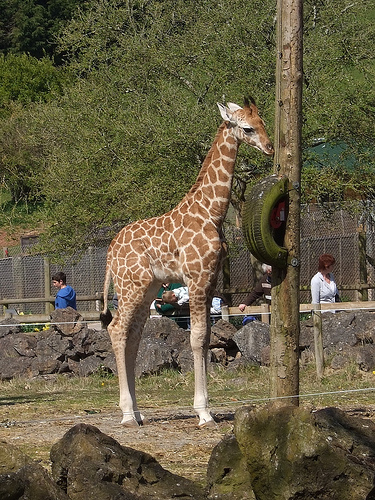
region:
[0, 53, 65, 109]
green leaves on tree top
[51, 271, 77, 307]
boy wearing blue hoodie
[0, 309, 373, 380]
uneven stone wall of enclosure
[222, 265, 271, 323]
man with hand on wood fence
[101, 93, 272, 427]
side view of young standing giraffe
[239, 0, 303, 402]
wood pole with half tire under rope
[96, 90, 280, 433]
young brown and white giraffe standing near wooden pole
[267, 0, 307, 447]
thick brown wooden pole near giraffe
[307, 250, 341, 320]
woman wearing white shirt walking near giraffe enclosure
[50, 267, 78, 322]
person wearing blue coat walking near giraffe enclosure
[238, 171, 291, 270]
green and black half of tire attached to wooden pole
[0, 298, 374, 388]
light brown wooden fence around giraffe enclosure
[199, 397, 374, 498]
large gray black and green stone near giraffe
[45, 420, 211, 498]
large black green and gray rock near giraffe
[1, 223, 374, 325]
tall metal fence near giraffe enclosure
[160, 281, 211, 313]
person wearing white outfit hanging over side of fence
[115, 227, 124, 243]
brown spot on giraffe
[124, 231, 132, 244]
brown spot on giraffe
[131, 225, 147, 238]
brown spot on giraffe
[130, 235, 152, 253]
brown spot on giraffe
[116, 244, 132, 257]
brown spot on giraffe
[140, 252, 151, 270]
brown spot on giraffe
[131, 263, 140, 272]
brown spot on giraffe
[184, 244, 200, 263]
brown spot on giraffe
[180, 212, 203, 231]
brown spot on giraffe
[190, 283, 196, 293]
brown spot on giraffe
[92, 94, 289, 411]
The giraffe is a young one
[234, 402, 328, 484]
The moss is green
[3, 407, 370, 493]
The three rocks in the front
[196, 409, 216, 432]
The front hooves of the giraffe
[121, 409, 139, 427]
The back hooves of the giraffe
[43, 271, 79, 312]
The boy in the blue hoodie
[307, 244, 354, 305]
The woman in the white shirt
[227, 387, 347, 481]
The rock has moss on it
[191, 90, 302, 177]
giraffe touching nose to pole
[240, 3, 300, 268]
semicircle of green tire attached to pole by ropes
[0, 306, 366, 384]
rocks forming partition behind giraffes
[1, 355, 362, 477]
grass and straw covering ground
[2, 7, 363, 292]
trees grown over wire and wooden fencing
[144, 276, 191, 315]
child leaning over wire behind giraffe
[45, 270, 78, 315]
boy in blue sweatshirt in front of railing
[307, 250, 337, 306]
woman in white sweater behind railing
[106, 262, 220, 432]
giraffe standing with legs close together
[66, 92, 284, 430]
The giraffe is standing above the tire on the pole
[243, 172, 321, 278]
The tire has been mounted on the side of the wooden pole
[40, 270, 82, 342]
The boy is wearing a blue sweatshirt in the zoo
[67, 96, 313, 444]
The giraffe has its nose against the pole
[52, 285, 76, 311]
the jacket is blue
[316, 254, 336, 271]
the hair is red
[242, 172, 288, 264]
the green moss on the tire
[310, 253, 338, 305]
the woman has red hair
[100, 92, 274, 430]
the giraffe is tall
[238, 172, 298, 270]
half tire in wood post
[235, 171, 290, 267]
green painted auto tire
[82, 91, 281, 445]
standing giraffe facing right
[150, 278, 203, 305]
small child laying face down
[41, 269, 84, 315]
young man in blue hoodie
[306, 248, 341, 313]
adult female with red hair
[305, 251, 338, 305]
woman in white shirt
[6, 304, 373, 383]
low stone wall behind giraffe